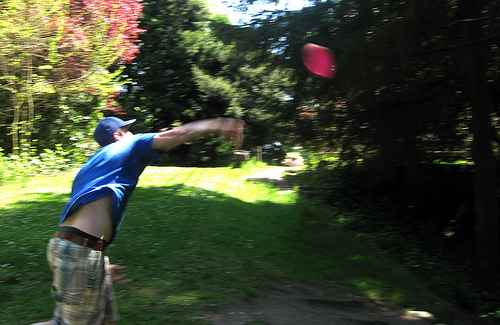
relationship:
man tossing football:
[46, 108, 255, 318] [293, 33, 366, 81]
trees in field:
[161, 8, 285, 133] [173, 169, 383, 309]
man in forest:
[46, 108, 255, 318] [239, 24, 482, 280]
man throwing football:
[46, 108, 255, 318] [302, 43, 340, 79]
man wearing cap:
[46, 108, 255, 318] [86, 111, 139, 141]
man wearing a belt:
[46, 108, 255, 318] [44, 226, 109, 254]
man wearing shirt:
[46, 108, 255, 318] [69, 132, 165, 231]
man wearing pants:
[46, 108, 255, 318] [46, 234, 118, 324]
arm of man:
[137, 119, 247, 149] [46, 108, 255, 318]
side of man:
[89, 155, 132, 248] [46, 108, 255, 318]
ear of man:
[113, 129, 126, 144] [46, 108, 255, 318]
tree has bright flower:
[75, 6, 162, 62] [122, 12, 137, 22]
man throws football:
[46, 108, 255, 318] [302, 43, 340, 79]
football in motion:
[302, 43, 340, 79] [285, 44, 329, 80]